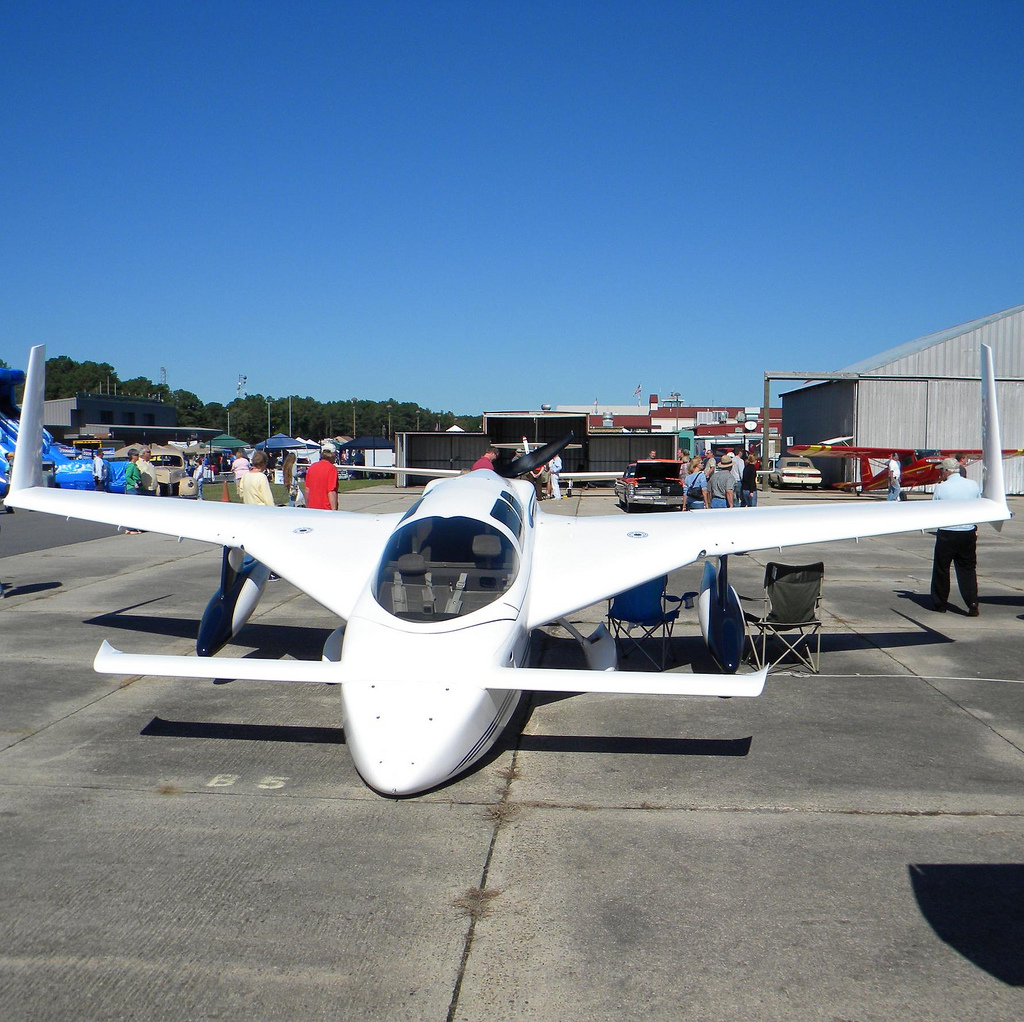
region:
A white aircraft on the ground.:
[0, 340, 1015, 790]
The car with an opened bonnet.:
[624, 443, 689, 501]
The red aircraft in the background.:
[803, 437, 1016, 496]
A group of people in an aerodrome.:
[90, 437, 988, 656]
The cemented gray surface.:
[0, 479, 1023, 1018]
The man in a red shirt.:
[308, 446, 340, 504]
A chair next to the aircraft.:
[755, 563, 826, 675]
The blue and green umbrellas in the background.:
[210, 430, 308, 472]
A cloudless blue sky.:
[0, 0, 1022, 412]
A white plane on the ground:
[1, 354, 1007, 795]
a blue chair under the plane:
[610, 579, 669, 638]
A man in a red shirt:
[307, 437, 346, 511]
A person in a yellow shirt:
[231, 458, 280, 503]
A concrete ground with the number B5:
[19, 695, 356, 1012]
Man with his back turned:
[927, 455, 982, 612]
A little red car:
[611, 452, 688, 506]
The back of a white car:
[775, 442, 827, 493]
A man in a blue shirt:
[931, 454, 980, 610]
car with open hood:
[614, 456, 694, 514]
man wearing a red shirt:
[302, 437, 345, 515]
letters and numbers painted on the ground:
[209, 764, 292, 794]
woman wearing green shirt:
[118, 442, 145, 499]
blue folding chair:
[601, 564, 700, 673]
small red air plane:
[782, 428, 1017, 504]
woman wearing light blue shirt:
[677, 453, 713, 517]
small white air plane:
[2, 336, 1020, 821]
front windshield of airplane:
[362, 513, 525, 628]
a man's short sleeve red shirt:
[305, 459, 338, 511]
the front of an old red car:
[614, 448, 688, 512]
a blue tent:
[258, 426, 313, 458]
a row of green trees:
[193, 394, 482, 445]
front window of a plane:
[368, 502, 517, 619]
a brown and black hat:
[715, 452, 739, 468]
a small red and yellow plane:
[782, 432, 1021, 497]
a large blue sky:
[1, 0, 1020, 401]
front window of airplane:
[363, 510, 528, 629]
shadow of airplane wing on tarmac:
[133, 698, 763, 768]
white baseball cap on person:
[309, 435, 344, 464]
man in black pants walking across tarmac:
[910, 445, 990, 623]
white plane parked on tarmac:
[0, 315, 1019, 812]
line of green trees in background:
[2, 347, 484, 447]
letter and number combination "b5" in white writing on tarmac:
[195, 756, 301, 805]